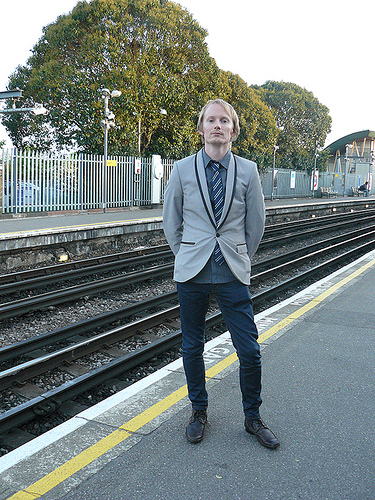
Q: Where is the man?
A: Train stop.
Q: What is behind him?
A: Trees.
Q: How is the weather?
A: Sunny.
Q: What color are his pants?
A: Blue.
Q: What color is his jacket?
A: Grey.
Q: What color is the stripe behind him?
A: Yellow.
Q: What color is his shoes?
A: Brown.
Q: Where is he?
A: Train stop.